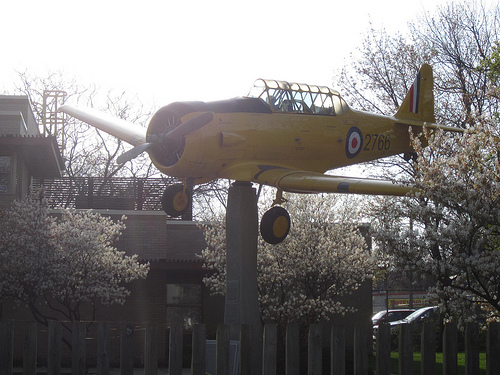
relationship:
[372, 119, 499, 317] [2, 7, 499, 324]
blossoms on trees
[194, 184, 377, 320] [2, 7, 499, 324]
blossoms on trees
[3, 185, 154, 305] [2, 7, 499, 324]
blossoms on trees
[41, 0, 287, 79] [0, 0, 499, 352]
light over trees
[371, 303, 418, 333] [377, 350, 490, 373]
car parked by lawn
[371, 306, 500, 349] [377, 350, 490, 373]
car parked by lawn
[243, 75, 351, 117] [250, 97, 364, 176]
frame over cockpit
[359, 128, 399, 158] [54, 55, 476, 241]
numbers on plane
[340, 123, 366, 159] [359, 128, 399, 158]
rings next  to numbers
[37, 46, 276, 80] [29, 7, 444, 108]
clouds in sky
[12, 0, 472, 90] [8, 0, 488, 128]
clouds are in sky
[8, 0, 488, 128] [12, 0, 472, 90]
sky has clouds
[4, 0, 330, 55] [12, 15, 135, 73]
sky has clouds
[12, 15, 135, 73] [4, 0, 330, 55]
clouds are in sky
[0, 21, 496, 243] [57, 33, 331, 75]
sky with clouds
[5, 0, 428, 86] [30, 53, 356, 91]
clouds in sky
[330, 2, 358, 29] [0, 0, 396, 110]
white clouds with sky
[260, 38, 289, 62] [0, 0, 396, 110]
white clouds with sky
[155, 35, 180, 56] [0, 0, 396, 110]
white clouds with sky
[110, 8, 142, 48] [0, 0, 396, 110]
white clouds with sky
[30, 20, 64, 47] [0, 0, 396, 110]
white clouds with sky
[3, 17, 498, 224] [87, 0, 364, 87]
sky with clouds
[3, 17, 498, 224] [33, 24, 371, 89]
sky with clouds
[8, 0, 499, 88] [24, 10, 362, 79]
sky with clouds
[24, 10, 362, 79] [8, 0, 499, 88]
clouds in sky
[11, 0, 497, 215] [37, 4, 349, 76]
sky has clouds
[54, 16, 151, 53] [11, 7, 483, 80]
clouds high in sky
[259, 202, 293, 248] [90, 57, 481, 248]
wheel on plane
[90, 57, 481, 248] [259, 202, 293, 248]
plane has wheel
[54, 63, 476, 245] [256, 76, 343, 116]
airplane with cockpit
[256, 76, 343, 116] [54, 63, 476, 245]
cockpit on top airplane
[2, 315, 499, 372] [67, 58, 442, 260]
fence below plane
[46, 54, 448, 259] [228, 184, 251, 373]
airplane attached to post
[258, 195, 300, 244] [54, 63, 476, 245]
landing gear attached to airplane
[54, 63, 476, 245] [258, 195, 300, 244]
airplane has landing gear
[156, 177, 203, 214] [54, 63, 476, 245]
landing gear on airplane